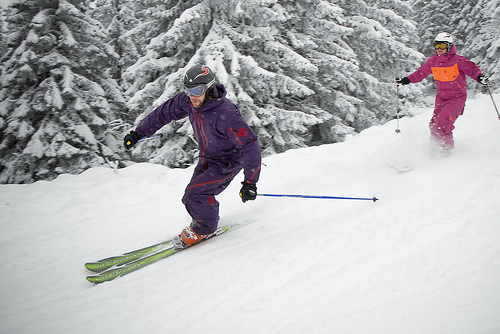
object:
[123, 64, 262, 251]
man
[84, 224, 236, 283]
skis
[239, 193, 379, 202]
pole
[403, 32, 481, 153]
snowsuit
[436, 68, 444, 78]
orange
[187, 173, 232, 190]
stripes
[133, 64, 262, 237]
snowsuit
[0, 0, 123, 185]
pine trees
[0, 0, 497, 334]
snow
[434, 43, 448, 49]
goggles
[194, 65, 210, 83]
markings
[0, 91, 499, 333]
ground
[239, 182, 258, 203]
glove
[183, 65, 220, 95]
helmet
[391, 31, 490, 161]
person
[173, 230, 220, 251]
boots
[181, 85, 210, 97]
goggles